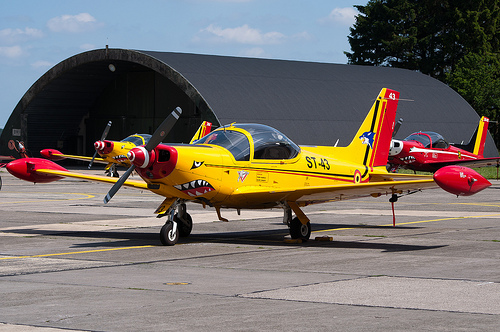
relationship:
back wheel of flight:
[291, 216, 313, 239] [2, 86, 483, 246]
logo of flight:
[358, 128, 377, 150] [2, 86, 483, 246]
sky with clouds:
[1, 0, 372, 130] [1, 10, 111, 64]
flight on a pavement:
[2, 87, 497, 245] [2, 249, 492, 303]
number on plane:
[320, 159, 331, 174] [4, 81, 499, 247]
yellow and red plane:
[284, 176, 300, 186] [99, 89, 484, 245]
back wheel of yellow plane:
[291, 216, 313, 239] [81, 72, 448, 245]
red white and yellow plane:
[441, 171, 459, 182] [127, 87, 416, 238]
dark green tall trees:
[393, 17, 426, 40] [350, 3, 477, 73]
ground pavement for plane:
[14, 245, 464, 329] [67, 63, 436, 243]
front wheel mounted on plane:
[160, 220, 180, 247] [4, 81, 499, 247]